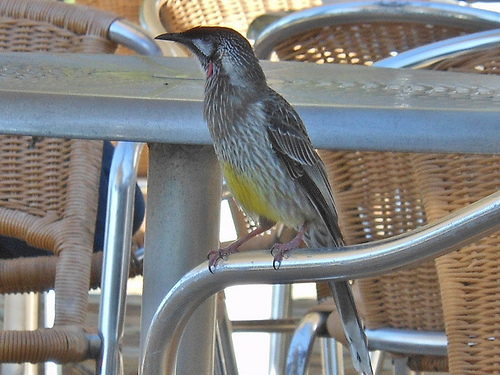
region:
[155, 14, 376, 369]
bird perched on chair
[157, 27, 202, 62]
black beak of bird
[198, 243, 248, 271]
foot of bird on chair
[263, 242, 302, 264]
foot of bird on chair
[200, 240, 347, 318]
metal arm of chair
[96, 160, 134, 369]
metal arm of chair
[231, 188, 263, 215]
yellow belly feathers on bird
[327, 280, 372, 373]
long tail feathers of bird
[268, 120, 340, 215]
side wings of bird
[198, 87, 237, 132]
neck feathers of bird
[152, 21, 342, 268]
this is a bird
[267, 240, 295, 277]
the claw of a bird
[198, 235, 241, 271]
the claw of a bird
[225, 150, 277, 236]
this is a yellow patch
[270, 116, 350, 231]
the wing of a bird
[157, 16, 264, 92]
the head of a bird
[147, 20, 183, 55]
the beak of a bird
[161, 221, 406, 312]
the bird is standing on a metal rail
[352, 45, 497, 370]
This is a chair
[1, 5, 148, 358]
This is a chair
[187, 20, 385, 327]
a bird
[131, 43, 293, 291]
a bird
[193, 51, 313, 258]
a bird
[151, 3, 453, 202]
a bird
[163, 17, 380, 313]
a bird on an armchair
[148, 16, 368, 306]
bird with a yellow underbelly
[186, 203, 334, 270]
bird claws on a handrail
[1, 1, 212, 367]
wooden woven chair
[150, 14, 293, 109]
bird's head with a black beak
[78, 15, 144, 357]
silver metal leg of the wooden chair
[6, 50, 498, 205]
silver table next to the bird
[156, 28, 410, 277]
bird standing on a railing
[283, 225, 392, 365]
birds tail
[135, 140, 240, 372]
table stand holding the table up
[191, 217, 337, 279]
birds legs